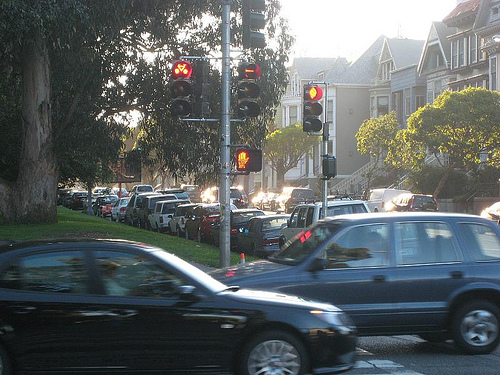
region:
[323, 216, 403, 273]
window of a car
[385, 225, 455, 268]
window of a car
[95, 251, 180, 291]
window of a car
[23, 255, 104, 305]
window of a car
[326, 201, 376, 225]
window of a car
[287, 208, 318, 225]
window of a car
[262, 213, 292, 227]
window of a car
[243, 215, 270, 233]
window of a car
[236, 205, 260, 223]
window of a car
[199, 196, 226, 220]
window of a car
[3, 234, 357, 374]
A black car driving by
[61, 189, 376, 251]
A long row of parked cars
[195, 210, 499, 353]
A small SUV driving by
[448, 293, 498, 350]
The rear wheel of a vehicle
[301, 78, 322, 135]
A traffic light showing red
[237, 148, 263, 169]
A crosswalk signal showing a hand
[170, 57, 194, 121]
Traffic light showing red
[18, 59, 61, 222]
Large trunk of a tree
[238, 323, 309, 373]
Front wheel on a car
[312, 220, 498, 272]
Windows on the side of a vehicle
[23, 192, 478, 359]
multiple cars on the street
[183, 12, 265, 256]
light up street signs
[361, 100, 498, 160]
tree with many green leaves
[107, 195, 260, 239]
many cars parked on the street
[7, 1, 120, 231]
large tree trunk with many leaves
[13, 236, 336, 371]
black car on the road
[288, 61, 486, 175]
multiple houses across the street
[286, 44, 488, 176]
large houses in the back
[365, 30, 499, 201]
houses behind a green tree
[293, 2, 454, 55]
sky with no clouds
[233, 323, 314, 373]
one right front vehicle wheel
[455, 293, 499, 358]
one back left car wheel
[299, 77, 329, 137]
traffic light with red illuminated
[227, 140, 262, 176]
traffic light with illuminated hand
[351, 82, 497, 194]
sunlit green leafy trees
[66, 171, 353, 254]
row of parked cars on city street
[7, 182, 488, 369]
two dark cars passing each other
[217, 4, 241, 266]
one shiny metal pole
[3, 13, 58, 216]
one large shadowed tree trunk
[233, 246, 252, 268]
top of one orange traffic cone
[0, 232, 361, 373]
Car on the street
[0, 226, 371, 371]
Car is on the street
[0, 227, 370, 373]
Car on the road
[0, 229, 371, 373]
Car is on the road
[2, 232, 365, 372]
Black car on the street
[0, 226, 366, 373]
Black car is on the street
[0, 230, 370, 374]
Black car on the road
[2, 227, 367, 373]
Black car is on the road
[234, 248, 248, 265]
Orange cone on the sidewalk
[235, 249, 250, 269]
Orange cone is on the sidewalk